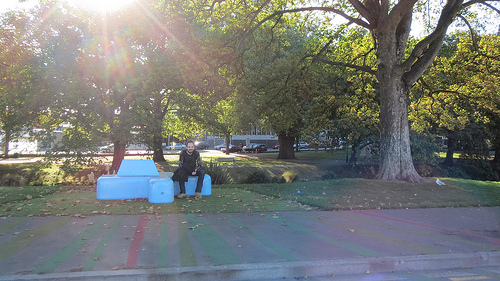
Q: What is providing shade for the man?
A: Trees.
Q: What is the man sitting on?
A: Blue bench.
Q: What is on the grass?
A: Leaves.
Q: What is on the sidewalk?
A: Green, red, yellow stripes.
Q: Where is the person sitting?
A: Bench.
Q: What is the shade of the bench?
A: Blue.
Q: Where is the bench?
A: Park.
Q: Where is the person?
A: Sitting outside.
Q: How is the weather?
A: Sunny.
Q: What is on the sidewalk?
A: Red paint.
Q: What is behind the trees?
A: Parking lot.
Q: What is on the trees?
A: Leaves.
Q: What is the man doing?
A: Sitting.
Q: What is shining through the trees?
A: The sun.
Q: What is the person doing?
A: Sitting down.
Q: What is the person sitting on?
A: A blue bench.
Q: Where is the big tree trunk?
A: On the right.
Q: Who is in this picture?
A: A man.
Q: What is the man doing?
A: Sitting.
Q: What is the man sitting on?
A: A sculpture bench.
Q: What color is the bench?
A: Light blue.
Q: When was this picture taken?
A: During the day.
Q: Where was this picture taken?
A: In a park.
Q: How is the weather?
A: Sunny.